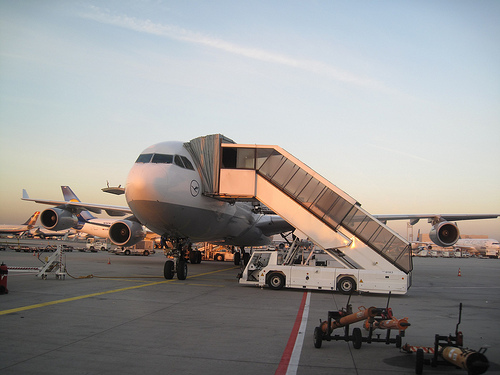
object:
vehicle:
[236, 229, 413, 295]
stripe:
[271, 291, 312, 375]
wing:
[346, 213, 500, 247]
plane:
[21, 133, 500, 295]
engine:
[108, 220, 147, 247]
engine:
[429, 221, 460, 247]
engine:
[39, 205, 79, 230]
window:
[135, 153, 196, 171]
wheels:
[164, 257, 187, 280]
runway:
[1, 249, 498, 375]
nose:
[127, 167, 158, 199]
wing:
[20, 185, 148, 247]